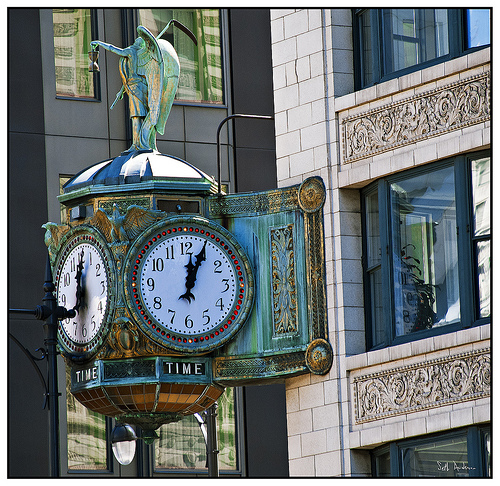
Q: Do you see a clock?
A: Yes, there is a clock.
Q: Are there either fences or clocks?
A: Yes, there is a clock.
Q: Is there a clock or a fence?
A: Yes, there is a clock.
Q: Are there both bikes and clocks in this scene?
A: No, there is a clock but no bikes.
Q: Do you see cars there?
A: No, there are no cars.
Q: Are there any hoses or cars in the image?
A: No, there are no cars or hoses.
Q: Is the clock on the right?
A: No, the clock is on the left of the image.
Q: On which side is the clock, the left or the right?
A: The clock is on the left of the image.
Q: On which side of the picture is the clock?
A: The clock is on the left of the image.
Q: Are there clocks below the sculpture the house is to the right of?
A: Yes, there is a clock below the sculpture.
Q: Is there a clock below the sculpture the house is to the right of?
A: Yes, there is a clock below the sculpture.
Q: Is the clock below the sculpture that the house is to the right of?
A: Yes, the clock is below the sculpture.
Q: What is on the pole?
A: The clock is on the pole.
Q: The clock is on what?
A: The clock is on the pole.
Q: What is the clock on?
A: The clock is on the pole.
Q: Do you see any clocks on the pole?
A: Yes, there is a clock on the pole.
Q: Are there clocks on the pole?
A: Yes, there is a clock on the pole.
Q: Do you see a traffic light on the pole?
A: No, there is a clock on the pole.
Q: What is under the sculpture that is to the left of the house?
A: The clock is under the sculpture.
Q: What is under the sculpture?
A: The clock is under the sculpture.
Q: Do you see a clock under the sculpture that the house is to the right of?
A: Yes, there is a clock under the sculpture.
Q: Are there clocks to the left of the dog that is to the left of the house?
A: Yes, there is a clock to the left of the dog.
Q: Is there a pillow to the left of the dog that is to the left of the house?
A: No, there is a clock to the left of the dog.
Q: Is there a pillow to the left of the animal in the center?
A: No, there is a clock to the left of the dog.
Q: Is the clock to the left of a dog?
A: Yes, the clock is to the left of a dog.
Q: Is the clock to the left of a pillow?
A: No, the clock is to the left of a dog.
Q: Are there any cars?
A: No, there are no cars.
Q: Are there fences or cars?
A: No, there are no cars or fences.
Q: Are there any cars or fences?
A: No, there are no cars or fences.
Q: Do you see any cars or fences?
A: No, there are no cars or fences.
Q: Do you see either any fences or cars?
A: No, there are no cars or fences.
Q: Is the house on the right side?
A: Yes, the house is on the right of the image.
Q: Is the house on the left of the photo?
A: No, the house is on the right of the image.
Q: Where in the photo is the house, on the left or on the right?
A: The house is on the right of the image.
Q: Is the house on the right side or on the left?
A: The house is on the right of the image.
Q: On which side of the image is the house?
A: The house is on the right of the image.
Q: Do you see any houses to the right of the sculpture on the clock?
A: Yes, there is a house to the right of the sculpture.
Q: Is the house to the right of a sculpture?
A: Yes, the house is to the right of a sculpture.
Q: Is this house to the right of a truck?
A: No, the house is to the right of a sculpture.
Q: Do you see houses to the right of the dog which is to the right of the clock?
A: Yes, there is a house to the right of the dog.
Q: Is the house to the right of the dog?
A: Yes, the house is to the right of the dog.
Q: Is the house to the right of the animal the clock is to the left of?
A: Yes, the house is to the right of the dog.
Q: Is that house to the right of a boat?
A: No, the house is to the right of the dog.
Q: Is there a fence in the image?
A: No, there are no fences.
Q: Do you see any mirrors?
A: No, there are no mirrors.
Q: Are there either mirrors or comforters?
A: No, there are no mirrors or comforters.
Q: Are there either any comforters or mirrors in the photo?
A: No, there are no mirrors or comforters.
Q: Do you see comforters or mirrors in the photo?
A: No, there are no mirrors or comforters.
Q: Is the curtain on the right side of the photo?
A: Yes, the curtain is on the right of the image.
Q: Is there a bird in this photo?
A: No, there are no birds.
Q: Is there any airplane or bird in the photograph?
A: No, there are no birds or airplanes.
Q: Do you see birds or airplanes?
A: No, there are no birds or airplanes.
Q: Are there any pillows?
A: No, there are no pillows.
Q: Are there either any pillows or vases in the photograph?
A: No, there are no pillows or vases.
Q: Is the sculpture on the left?
A: Yes, the sculpture is on the left of the image.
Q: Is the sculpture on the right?
A: No, the sculpture is on the left of the image.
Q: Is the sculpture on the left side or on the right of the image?
A: The sculpture is on the left of the image.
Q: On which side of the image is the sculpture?
A: The sculpture is on the left of the image.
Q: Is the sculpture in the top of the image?
A: Yes, the sculpture is in the top of the image.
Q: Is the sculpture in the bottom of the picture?
A: No, the sculpture is in the top of the image.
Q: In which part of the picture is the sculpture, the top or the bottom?
A: The sculpture is in the top of the image.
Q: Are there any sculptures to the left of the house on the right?
A: Yes, there is a sculpture to the left of the house.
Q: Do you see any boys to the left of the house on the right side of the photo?
A: No, there is a sculpture to the left of the house.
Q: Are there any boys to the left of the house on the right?
A: No, there is a sculpture to the left of the house.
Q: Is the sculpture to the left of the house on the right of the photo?
A: Yes, the sculpture is to the left of the house.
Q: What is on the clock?
A: The sculpture is on the clock.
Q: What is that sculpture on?
A: The sculpture is on the clock.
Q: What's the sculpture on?
A: The sculpture is on the clock.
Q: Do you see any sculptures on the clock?
A: Yes, there is a sculpture on the clock.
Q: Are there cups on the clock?
A: No, there is a sculpture on the clock.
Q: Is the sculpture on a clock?
A: Yes, the sculpture is on a clock.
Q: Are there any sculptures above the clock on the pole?
A: Yes, there is a sculpture above the clock.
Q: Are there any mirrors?
A: No, there are no mirrors.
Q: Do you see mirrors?
A: No, there are no mirrors.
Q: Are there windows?
A: Yes, there is a window.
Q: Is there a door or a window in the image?
A: Yes, there is a window.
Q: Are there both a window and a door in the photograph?
A: No, there is a window but no doors.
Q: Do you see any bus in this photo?
A: No, there are no buses.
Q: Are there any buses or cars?
A: No, there are no buses or cars.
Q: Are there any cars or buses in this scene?
A: No, there are no buses or cars.